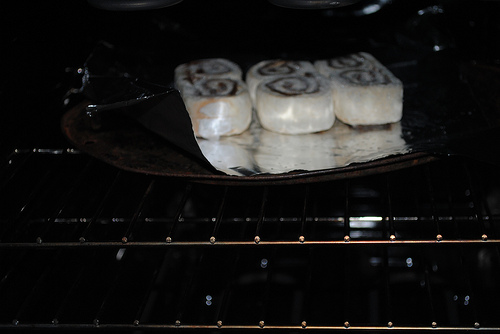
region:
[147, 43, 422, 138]
cinnamon rolls in the oven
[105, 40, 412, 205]
cinnamon rolls are white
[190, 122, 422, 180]
a piece of aluminum foil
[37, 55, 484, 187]
a pan inside an oven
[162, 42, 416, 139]
cakes being baked inside oven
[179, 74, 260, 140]
a pound cake with chocolate filling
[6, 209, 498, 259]
the trays inside the oven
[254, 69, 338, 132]
swirl design in the middle of cake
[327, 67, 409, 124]
swirl design in the middle of cake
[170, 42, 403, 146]
six cake being baked inside oven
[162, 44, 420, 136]
vanilla pond cakes being bake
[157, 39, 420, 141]
six swirl style vanilla cakes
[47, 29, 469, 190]
the pan is on the rack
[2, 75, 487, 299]
the rack is in the oven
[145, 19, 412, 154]
the cinnamon buns are on the foil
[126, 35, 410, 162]
the bus are white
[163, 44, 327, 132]
a brown swirl in the buns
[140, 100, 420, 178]
the foil is silver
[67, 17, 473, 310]
the oven is dark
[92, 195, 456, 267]
the oven rack is made of metal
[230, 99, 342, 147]
light from the foil reflected on the buns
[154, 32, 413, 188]
the buns are not cooked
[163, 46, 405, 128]
a hald dozen uncooked cinnamom rolls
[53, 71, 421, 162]
a foil covered sheet for baking rolls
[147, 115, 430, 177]
reflection of rolls on the sheet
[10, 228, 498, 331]
ends of two separate oven racks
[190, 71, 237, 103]
cinnamon swirled in the roll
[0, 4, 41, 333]
side wall of the oven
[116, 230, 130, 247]
end of spoke on the rack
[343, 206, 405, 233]
reflection of light in back of oven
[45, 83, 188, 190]
end of sheet is curled up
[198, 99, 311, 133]
light from foil reflected on the dough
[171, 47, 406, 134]
rolls in the oven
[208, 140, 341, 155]
tinfoil on the pan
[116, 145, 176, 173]
pan that the tinfoil is on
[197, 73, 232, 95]
swirls on the buns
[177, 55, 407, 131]
six buns on the tinfoil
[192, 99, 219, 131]
orange on the bun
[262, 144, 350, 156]
reflection of the buns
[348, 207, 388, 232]
shiny spot in the oven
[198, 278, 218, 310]
spot inside the oven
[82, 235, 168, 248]
silver part of the rack